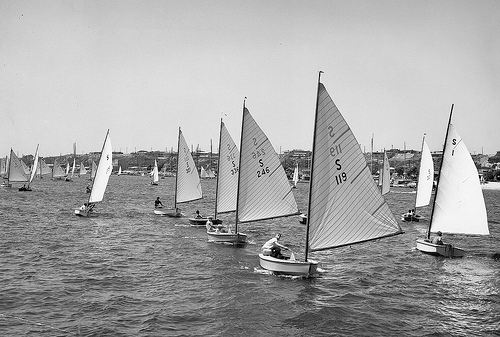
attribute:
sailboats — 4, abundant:
[43, 142, 469, 256]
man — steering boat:
[265, 232, 295, 257]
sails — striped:
[171, 125, 391, 234]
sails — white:
[420, 130, 481, 229]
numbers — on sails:
[334, 152, 354, 180]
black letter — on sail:
[445, 141, 467, 154]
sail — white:
[434, 107, 484, 254]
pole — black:
[437, 112, 445, 241]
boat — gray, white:
[157, 132, 201, 219]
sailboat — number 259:
[87, 133, 133, 220]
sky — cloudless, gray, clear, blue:
[198, 28, 275, 59]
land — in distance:
[117, 150, 152, 164]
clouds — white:
[364, 39, 425, 63]